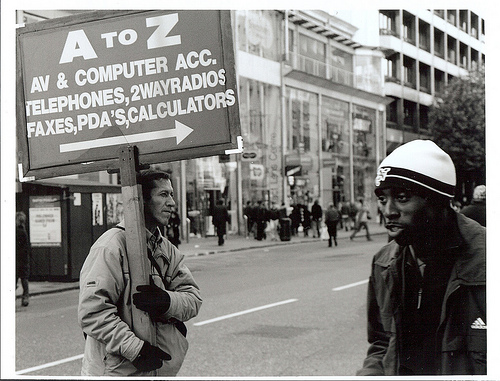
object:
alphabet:
[56, 16, 179, 60]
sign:
[27, 14, 237, 167]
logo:
[469, 315, 486, 333]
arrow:
[49, 121, 196, 153]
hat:
[378, 139, 464, 204]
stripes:
[378, 168, 459, 202]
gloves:
[127, 341, 171, 374]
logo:
[238, 149, 259, 160]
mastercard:
[244, 153, 254, 158]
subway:
[287, 168, 296, 174]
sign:
[285, 160, 305, 181]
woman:
[18, 211, 34, 308]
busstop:
[15, 187, 119, 285]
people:
[348, 209, 371, 246]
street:
[12, 224, 410, 377]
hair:
[468, 182, 484, 201]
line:
[203, 288, 299, 333]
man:
[365, 129, 485, 375]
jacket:
[361, 212, 486, 377]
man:
[75, 169, 200, 374]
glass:
[325, 108, 347, 150]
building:
[285, 8, 363, 208]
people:
[243, 197, 253, 238]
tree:
[428, 64, 486, 186]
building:
[378, 8, 480, 179]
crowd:
[194, 196, 376, 242]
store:
[238, 82, 277, 202]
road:
[16, 227, 411, 375]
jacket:
[74, 220, 207, 379]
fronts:
[237, 33, 388, 158]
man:
[325, 208, 336, 250]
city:
[17, 6, 483, 377]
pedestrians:
[208, 190, 367, 216]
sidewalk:
[170, 232, 342, 254]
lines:
[219, 281, 348, 326]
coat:
[358, 206, 486, 380]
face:
[377, 195, 415, 232]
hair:
[136, 165, 166, 202]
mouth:
[385, 224, 402, 241]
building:
[14, 183, 132, 276]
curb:
[20, 265, 85, 307]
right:
[168, 121, 199, 147]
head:
[138, 164, 188, 229]